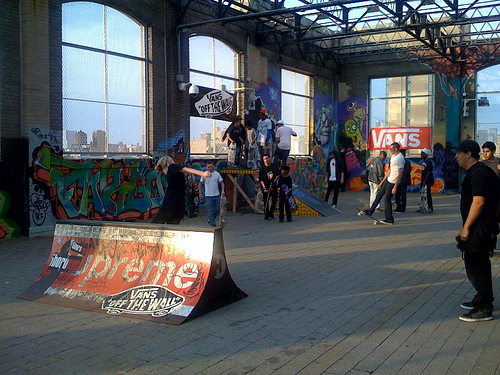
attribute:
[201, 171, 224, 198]
shirt — white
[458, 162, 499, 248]
shirt — black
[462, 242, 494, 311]
pants — black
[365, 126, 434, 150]
sign — red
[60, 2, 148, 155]
windows — big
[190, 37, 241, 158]
windows — big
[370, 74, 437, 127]
windows — big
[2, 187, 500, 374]
floor — grey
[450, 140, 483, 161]
hat — black